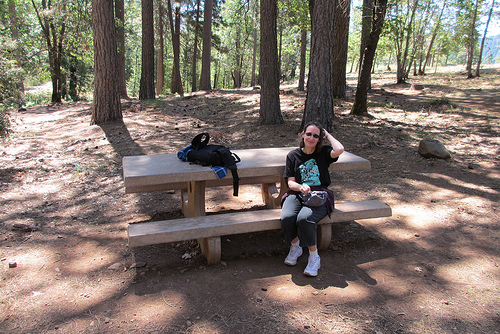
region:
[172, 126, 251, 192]
black backpack laying on table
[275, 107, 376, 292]
woman sitting on wooden bench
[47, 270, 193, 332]
ground covered in dirt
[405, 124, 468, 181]
large rock laying on ground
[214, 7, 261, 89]
trees covered in green leaves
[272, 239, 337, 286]
white tennis shoes on woman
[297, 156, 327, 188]
design on front of woman's shirt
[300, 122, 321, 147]
pair of black sun glasses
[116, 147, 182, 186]
brown wooden table top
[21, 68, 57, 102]
grey pavement on road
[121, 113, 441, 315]
Woman on the picnic table.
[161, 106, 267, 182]
Bag on the picnic table.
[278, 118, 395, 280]
Woman who is sitting.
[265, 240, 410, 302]
Shadow on the ground.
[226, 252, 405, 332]
Sunlight on the ground.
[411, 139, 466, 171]
Rock on the ground.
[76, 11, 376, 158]
Trunks of the tree.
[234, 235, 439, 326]
White shoes on the woman.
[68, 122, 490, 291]
Picnic table in a forest.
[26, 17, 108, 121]
Leaves on the tree.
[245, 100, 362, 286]
a woman sitting on a bench.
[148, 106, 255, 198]
a bag on a bench.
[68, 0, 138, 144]
a tree in a forest.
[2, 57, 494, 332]
dirt ground in a forest.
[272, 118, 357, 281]
a woman wearing white shoes.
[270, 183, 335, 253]
a dark pair of pants.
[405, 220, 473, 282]
a section of shadow.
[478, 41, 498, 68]
a distant hillside.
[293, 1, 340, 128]
a tall brown tree.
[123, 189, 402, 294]
a seat on a bench.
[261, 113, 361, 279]
woman sitting on a bench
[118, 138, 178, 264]
table bench in a park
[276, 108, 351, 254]
woman wearing a black tshirt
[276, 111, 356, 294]
woman wearing a black pants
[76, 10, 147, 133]
tall tree trunk next to a bench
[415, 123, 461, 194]
rock on the ground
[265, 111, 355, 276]
woman wearing sun shades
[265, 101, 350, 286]
woman wearing white tennis shoes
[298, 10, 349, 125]
tall tree trunk next to bench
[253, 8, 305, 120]
tall tree trunk next to a bench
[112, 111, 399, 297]
a woman sitting at a picnic bench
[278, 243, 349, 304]
white shoes on her feet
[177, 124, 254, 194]
a black jacket on the table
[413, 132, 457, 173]
a large rock on the ground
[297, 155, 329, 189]
a blue design on black shirt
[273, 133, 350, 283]
a woman wears black pants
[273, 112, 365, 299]
a woman wears black shirt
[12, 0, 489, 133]
many tall trees in the park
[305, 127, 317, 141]
black glasses on woman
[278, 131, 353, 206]
woman wears a black shirt